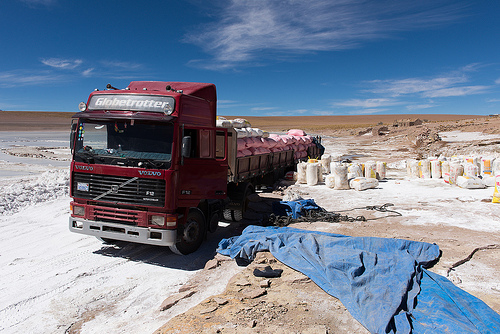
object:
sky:
[10, 8, 493, 73]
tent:
[224, 218, 497, 334]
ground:
[231, 276, 308, 327]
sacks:
[303, 159, 322, 185]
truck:
[67, 86, 297, 239]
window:
[177, 127, 204, 159]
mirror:
[69, 117, 79, 153]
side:
[68, 117, 85, 203]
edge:
[236, 228, 438, 249]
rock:
[248, 266, 282, 279]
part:
[255, 262, 275, 277]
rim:
[185, 218, 202, 246]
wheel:
[171, 203, 209, 255]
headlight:
[147, 211, 168, 228]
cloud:
[197, 11, 292, 63]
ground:
[319, 188, 479, 204]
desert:
[2, 104, 496, 139]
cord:
[267, 204, 403, 225]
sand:
[2, 214, 64, 271]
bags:
[238, 139, 251, 151]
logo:
[105, 180, 126, 193]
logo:
[90, 93, 174, 113]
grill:
[72, 178, 166, 200]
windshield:
[75, 117, 176, 167]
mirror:
[181, 133, 192, 161]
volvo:
[136, 165, 164, 176]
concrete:
[323, 150, 348, 160]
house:
[490, 113, 500, 120]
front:
[68, 112, 180, 246]